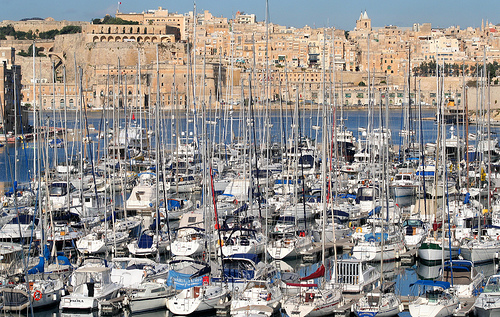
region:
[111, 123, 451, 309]
thee are ships on the sea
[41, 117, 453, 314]
the ships are motionless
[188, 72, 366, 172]
these are poles above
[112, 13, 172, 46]
this is a building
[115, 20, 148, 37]
the wall is brown in color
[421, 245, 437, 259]
the ship is white in color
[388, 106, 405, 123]
the water is blue in color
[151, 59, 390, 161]
the poles are thin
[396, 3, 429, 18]
this is the sky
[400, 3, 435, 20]
the sky is blue in color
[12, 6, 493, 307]
crowded tan buildings behind moored boats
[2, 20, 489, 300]
masts over of rows of boats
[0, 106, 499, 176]
angled blue waterway with small boats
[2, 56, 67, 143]
land under corner building jutting into water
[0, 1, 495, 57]
solid blue-gray sky over dense buildings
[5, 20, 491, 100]
buildings of same materials across town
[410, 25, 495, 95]
row of trees above flat roof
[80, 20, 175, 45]
wide buildings with row of entryways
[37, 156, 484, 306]
curved and flat panels on ends of boats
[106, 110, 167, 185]
largest boat at corner of last row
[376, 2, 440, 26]
this is the sky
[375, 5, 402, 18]
the sky is blue in color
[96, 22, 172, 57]
this is a building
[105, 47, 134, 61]
this is the wall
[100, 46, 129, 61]
the wall is brown in color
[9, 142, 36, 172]
this is a water body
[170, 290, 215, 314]
this is a ship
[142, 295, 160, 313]
the ship is white in color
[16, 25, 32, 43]
this is a tree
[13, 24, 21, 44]
the leaves are green ion color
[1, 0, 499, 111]
an ancient city in Europe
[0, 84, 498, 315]
boats of all types moored in the bay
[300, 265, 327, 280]
a burgundy color mainsail cover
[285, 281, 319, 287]
a burgundy color boom sail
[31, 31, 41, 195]
a sailboats main mast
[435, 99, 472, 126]
a ferry boat in the distance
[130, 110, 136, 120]
an orange marker buoy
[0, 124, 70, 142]
a concrete sea wall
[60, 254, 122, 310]
a motor boat cruiser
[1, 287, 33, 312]
an inflatable tender or dinghy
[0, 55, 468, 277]
huge harbor of ships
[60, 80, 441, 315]
group of ships docked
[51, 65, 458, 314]
large group of sail boats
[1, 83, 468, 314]
sail boats docked together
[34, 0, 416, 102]
many tan colored buildings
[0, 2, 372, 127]
buildings in background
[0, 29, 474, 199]
group of masts from boats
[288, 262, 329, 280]
red folded sail on boat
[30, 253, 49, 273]
blue folded sail on boat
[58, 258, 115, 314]
regular boat in the harbor